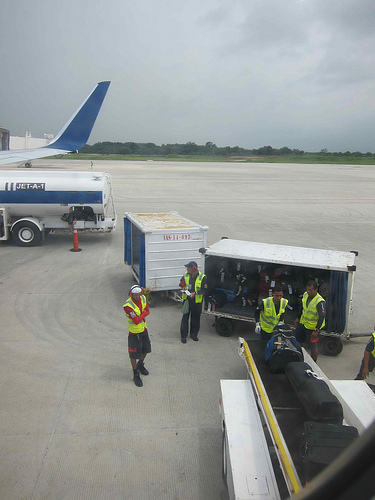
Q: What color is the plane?
A: White and blue.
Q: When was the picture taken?
A: Daytime.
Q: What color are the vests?
A: Yellow.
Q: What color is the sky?
A: Gray.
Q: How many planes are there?
A: One.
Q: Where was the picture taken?
A: At a Tarmac.